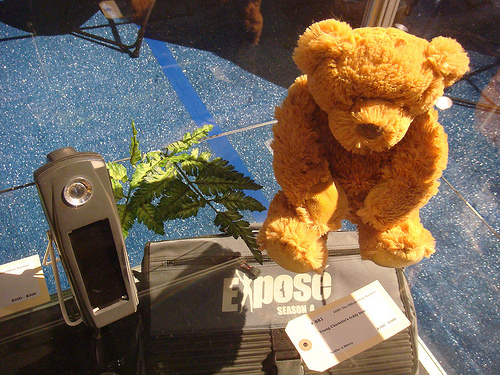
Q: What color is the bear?
A: Gold.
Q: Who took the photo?
A: Bears owner.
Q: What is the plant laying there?
A: Fern.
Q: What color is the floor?
A: Blue.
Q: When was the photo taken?
A: Daytime.